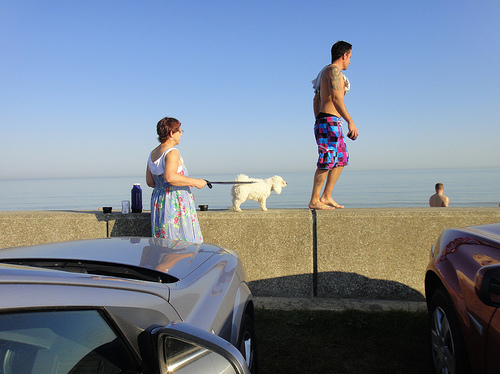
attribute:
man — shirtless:
[309, 41, 357, 208]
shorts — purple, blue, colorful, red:
[315, 113, 348, 170]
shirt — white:
[313, 69, 349, 94]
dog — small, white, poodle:
[231, 174, 287, 211]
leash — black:
[204, 177, 257, 189]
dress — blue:
[149, 146, 204, 244]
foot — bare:
[308, 199, 335, 210]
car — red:
[424, 223, 499, 372]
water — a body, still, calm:
[1, 166, 498, 212]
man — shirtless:
[430, 182, 449, 207]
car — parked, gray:
[0, 236, 254, 374]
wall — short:
[3, 205, 499, 298]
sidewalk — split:
[253, 295, 428, 326]